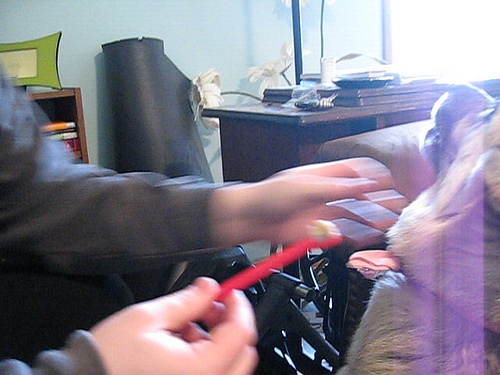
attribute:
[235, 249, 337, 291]
object — black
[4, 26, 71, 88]
picture frame — green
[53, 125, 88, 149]
books — orange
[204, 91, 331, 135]
desk — large, wood, big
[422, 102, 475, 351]
dog — backing, tan, beige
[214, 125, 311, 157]
table — background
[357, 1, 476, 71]
window — sunny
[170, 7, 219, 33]
walls — blue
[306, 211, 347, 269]
toothbrush — red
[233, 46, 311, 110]
flowers — tall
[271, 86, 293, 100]
material — black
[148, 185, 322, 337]
hands — white